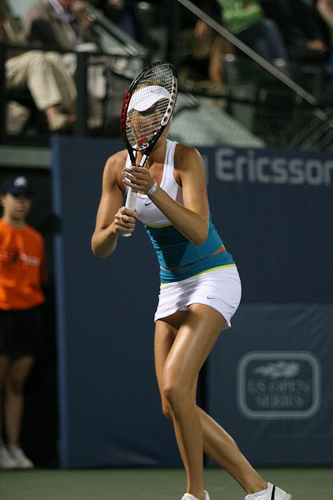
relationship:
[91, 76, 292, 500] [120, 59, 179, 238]
tennis holding racket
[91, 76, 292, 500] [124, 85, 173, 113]
tennis wearing a visor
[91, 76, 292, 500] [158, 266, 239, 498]
tennis has leg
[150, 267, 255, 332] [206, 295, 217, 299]
skirt has logo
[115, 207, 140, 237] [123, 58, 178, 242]
fingers around racket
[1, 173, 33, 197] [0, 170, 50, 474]
dark cap is on girl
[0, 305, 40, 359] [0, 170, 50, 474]
dark shorts is on girl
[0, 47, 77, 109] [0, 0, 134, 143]
slacks is on crowd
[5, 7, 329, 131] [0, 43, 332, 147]
people sitting in railing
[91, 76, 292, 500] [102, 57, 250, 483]
tennis playing tennis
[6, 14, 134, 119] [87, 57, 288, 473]
crowd watching tennis